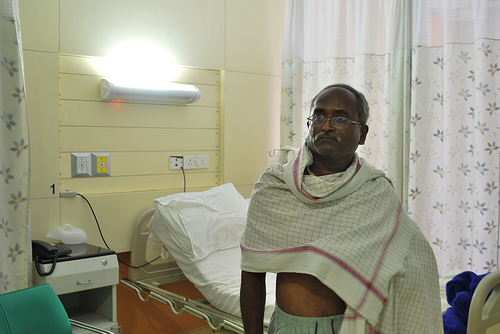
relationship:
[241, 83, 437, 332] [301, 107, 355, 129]
man wearing glasses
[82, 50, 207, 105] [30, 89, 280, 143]
light on a wall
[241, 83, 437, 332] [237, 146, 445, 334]
man wearing a sheet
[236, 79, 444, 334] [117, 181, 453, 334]
man next to bed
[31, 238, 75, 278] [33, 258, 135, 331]
phone on a stand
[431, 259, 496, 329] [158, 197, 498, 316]
shirt on top of bed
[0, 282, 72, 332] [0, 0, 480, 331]
chair in a room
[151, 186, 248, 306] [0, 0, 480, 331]
bed in a room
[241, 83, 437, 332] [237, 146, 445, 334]
man in a sheet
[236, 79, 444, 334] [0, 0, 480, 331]
man in a room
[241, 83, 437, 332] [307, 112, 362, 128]
man wearing glasses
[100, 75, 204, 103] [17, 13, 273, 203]
light fixture mounted on wall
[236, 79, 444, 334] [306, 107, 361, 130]
man wearing glasses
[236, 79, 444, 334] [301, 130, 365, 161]
man has a mustache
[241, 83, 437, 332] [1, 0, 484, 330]
man in hospital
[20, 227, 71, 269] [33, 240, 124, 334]
phone on stand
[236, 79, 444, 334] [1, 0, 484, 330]
man in hospital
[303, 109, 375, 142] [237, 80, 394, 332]
glasses on man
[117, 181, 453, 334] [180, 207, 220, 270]
bed with sheets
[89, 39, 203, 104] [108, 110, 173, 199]
light on wall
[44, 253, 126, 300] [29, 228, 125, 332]
drawer on table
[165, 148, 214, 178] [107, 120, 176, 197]
outlets on wall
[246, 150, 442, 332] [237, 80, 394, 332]
sheet on man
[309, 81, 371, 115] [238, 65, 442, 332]
grey hair on man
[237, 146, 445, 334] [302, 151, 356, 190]
sheet on neck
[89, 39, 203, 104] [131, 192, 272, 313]
light over bed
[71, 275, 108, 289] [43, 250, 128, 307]
knob on drawer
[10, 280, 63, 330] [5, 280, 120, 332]
back on chair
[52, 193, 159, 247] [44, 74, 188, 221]
cord on wall